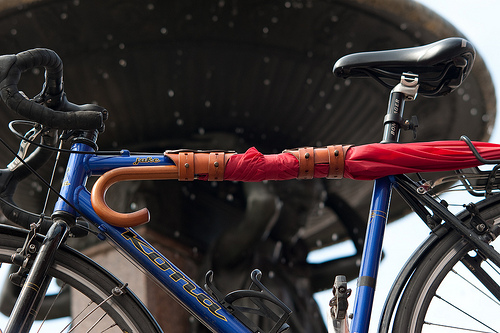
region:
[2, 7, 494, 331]
a bicycle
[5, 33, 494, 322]
a blue bicycle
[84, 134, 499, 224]
a red umbrella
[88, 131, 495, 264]
the umbrella has a wood handle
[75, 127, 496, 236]
the umbrella is strapped to the bicycle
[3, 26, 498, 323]
the bicycle is blue with black writing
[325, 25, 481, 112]
the bicycle seat is black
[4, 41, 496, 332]
the bicycle has a red umbrella strapped to it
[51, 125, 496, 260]
the umbrella is strapped on under the seat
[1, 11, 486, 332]
noone is riding the bicycle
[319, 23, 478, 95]
black seat of a bike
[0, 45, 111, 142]
black handlebars on a bike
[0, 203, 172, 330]
tire of a bike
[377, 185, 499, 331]
tire on a bike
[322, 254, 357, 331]
pedal of a bike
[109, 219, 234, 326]
black logo on a blue bike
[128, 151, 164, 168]
black logo on a blue bike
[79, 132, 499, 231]
red umbrella with brown handle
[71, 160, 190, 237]
brown umbrella handle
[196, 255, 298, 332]
black water bottle holder on bike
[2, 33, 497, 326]
parked bike at rest area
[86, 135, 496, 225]
red umbrella strapped on bike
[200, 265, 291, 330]
water bottle holder on bike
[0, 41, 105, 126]
handle bars on bike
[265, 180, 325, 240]
head of the statue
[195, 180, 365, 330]
statue in the background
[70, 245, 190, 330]
pillar holding statue up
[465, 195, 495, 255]
rear brakes on tire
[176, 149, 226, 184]
belt strap holding umbrella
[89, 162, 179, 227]
cane handle of umbrella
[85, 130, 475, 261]
umbrella attached to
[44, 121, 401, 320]
bike with blue frame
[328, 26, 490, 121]
bike saddle is black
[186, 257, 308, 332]
frame of bike with bottle holder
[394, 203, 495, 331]
bike tire is black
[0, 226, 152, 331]
bike tire is black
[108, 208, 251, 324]
black and yellow lettering on bike frame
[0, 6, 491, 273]
tall structure behind bike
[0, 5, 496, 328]
picture taken in broad daylight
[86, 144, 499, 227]
A closed pink umbrella with a brown handle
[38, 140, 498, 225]
Brown leather straps attaching an umbrella to a bicycle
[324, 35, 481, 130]
Black bicycle seat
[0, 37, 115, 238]
Bicycle handles wrapped in black tape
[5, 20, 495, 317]
A blue men's bicycle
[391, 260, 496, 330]
Thin metal spokes on a bicycle wheel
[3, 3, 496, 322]
Large grey fountain behind a bicycle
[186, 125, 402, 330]
Statue of a person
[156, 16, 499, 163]
Droplets of water falling from a fountain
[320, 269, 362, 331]
A bicycle pedal